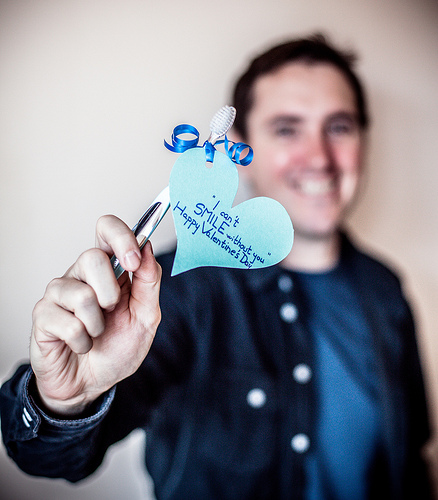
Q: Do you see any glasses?
A: No, there are no glasses.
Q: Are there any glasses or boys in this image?
A: No, there are no glasses or boys.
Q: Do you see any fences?
A: No, there are no fences.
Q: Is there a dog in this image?
A: No, there are no dogs.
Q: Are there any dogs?
A: No, there are no dogs.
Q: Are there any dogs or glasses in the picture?
A: No, there are no dogs or glasses.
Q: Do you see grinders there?
A: No, there are no grinders.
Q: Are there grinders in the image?
A: No, there are no grinders.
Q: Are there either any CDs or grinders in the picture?
A: No, there are no grinders or cds.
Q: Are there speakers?
A: Yes, there is a speaker.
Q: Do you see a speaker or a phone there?
A: Yes, there is a speaker.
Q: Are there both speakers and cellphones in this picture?
A: No, there is a speaker but no cell phones.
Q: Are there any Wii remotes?
A: No, there are no Wii remotes.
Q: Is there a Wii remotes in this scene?
A: No, there are no Wii controllers.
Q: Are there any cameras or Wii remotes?
A: No, there are no Wii remotes or cameras.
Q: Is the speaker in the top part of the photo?
A: Yes, the speaker is in the top of the image.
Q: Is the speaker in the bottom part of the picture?
A: No, the speaker is in the top of the image.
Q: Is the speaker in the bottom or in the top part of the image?
A: The speaker is in the top of the image.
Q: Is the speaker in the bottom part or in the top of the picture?
A: The speaker is in the top of the image.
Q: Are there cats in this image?
A: No, there are no cats.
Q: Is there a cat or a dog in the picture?
A: No, there are no cats or dogs.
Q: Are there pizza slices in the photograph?
A: No, there are no pizza slices.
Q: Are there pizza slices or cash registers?
A: No, there are no pizza slices or cash registers.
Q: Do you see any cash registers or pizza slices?
A: No, there are no pizza slices or cash registers.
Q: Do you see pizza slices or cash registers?
A: No, there are no pizza slices or cash registers.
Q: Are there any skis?
A: No, there are no skis.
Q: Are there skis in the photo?
A: No, there are no skis.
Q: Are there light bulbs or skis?
A: No, there are no skis or light bulbs.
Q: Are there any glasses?
A: No, there are no glasses.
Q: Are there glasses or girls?
A: No, there are no glasses or girls.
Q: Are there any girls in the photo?
A: No, there are no girls.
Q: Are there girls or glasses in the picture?
A: No, there are no girls or glasses.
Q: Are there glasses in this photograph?
A: No, there are no glasses.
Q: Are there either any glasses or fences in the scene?
A: No, there are no glasses or fences.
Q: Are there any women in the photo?
A: No, there are no women.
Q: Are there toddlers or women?
A: No, there are no women or toddlers.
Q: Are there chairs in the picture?
A: No, there are no chairs.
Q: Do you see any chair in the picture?
A: No, there are no chairs.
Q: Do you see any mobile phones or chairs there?
A: No, there are no chairs or mobile phones.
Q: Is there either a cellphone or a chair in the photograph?
A: No, there are no chairs or cell phones.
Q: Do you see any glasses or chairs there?
A: No, there are no glasses or chairs.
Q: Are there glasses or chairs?
A: No, there are no glasses or chairs.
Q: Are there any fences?
A: No, there are no fences.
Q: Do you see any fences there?
A: No, there are no fences.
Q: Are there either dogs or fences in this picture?
A: No, there are no fences or dogs.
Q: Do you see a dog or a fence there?
A: No, there are no fences or dogs.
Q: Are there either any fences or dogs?
A: No, there are no fences or dogs.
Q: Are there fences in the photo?
A: No, there are no fences.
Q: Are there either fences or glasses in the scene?
A: No, there are no fences or glasses.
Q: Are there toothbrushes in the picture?
A: Yes, there is a toothbrush.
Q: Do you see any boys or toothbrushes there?
A: Yes, there is a toothbrush.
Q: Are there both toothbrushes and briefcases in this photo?
A: No, there is a toothbrush but no briefcases.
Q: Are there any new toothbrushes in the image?
A: Yes, there is a new toothbrush.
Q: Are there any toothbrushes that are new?
A: Yes, there is a toothbrush that is new.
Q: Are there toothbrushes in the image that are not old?
A: Yes, there is an new toothbrush.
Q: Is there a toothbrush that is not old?
A: Yes, there is an new toothbrush.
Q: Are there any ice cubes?
A: No, there are no ice cubes.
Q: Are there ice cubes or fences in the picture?
A: No, there are no ice cubes or fences.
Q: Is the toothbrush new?
A: Yes, the toothbrush is new.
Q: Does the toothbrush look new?
A: Yes, the toothbrush is new.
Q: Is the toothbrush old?
A: No, the toothbrush is new.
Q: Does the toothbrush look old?
A: No, the toothbrush is new.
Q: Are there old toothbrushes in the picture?
A: No, there is a toothbrush but it is new.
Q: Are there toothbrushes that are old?
A: No, there is a toothbrush but it is new.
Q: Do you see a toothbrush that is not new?
A: No, there is a toothbrush but it is new.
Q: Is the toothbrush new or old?
A: The toothbrush is new.